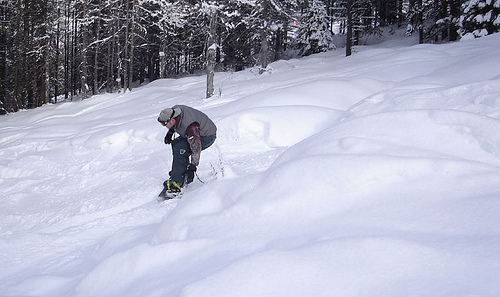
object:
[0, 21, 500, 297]
ground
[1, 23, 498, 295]
hill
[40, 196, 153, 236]
tracks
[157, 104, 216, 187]
man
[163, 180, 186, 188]
shoes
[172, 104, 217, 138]
jacket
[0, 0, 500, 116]
woods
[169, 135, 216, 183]
jeans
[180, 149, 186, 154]
patch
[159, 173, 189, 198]
skis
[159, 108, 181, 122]
hat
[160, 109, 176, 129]
head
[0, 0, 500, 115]
small tree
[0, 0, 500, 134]
small tree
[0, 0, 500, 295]
snow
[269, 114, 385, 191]
mound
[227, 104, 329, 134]
mound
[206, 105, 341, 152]
pile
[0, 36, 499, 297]
slope